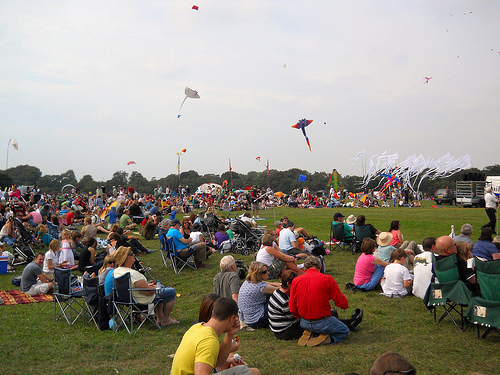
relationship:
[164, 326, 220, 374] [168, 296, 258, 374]
shirt on person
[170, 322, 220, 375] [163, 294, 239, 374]
shirt on person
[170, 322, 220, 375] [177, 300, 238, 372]
shirt on person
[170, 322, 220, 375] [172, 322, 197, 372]
shirt on back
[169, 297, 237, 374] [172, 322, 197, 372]
person has back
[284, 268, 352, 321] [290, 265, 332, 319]
shirt on person's back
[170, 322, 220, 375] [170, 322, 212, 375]
shirt on back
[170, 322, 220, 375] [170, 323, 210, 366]
shirt on person's back